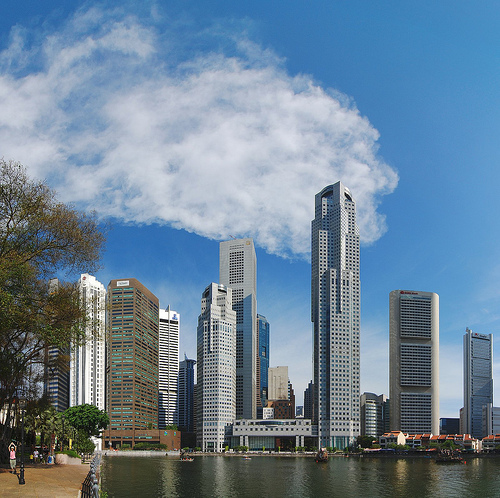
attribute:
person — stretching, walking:
[7, 441, 27, 478]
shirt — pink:
[7, 448, 21, 459]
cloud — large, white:
[125, 62, 378, 232]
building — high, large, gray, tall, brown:
[296, 162, 374, 449]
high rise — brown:
[102, 273, 179, 446]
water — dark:
[251, 469, 368, 496]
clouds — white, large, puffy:
[3, 11, 387, 269]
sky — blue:
[43, 5, 480, 166]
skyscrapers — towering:
[92, 183, 456, 438]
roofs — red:
[418, 430, 471, 442]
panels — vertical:
[112, 296, 167, 431]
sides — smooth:
[321, 226, 356, 441]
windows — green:
[111, 318, 137, 346]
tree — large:
[3, 167, 88, 377]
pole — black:
[17, 465, 28, 486]